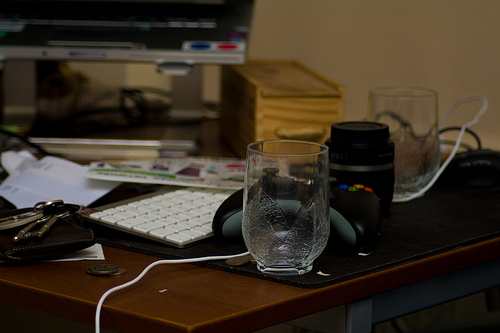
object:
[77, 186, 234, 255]
keyboard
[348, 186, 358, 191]
button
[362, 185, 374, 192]
button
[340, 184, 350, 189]
button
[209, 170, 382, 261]
controller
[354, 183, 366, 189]
button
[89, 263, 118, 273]
coins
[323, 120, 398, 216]
camera lens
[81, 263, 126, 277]
coins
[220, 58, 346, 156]
box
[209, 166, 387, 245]
xbox controller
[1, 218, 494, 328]
desk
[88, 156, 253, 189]
paper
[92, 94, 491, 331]
wire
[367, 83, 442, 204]
glass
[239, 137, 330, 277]
glass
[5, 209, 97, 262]
wallet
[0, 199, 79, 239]
keys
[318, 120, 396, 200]
spray can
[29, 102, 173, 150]
dvd player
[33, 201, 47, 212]
keyholder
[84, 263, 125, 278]
pennies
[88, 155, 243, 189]
cd